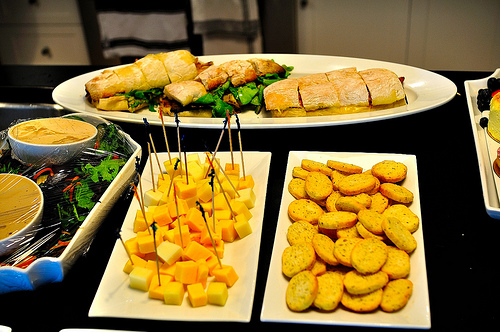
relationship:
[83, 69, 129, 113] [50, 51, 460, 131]
sandwich segment on top of plate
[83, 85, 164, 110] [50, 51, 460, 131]
sandwich segment on top of plate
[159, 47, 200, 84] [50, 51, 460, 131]
sandwich segment on top of plate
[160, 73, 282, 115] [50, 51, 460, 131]
sandwich segment on top of plate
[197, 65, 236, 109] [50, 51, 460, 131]
sandwich segment on top of plate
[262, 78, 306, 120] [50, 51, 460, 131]
sandwich segment on top of plate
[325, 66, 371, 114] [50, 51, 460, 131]
sandwich segment on top of plate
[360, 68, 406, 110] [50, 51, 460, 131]
sandwich segment on top of plate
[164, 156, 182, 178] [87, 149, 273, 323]
cheese cube on top of plate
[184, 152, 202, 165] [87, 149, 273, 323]
cheese cube on top of plate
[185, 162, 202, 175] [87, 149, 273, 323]
cheese cube on top of plate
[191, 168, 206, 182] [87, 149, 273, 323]
cheese cube on top of plate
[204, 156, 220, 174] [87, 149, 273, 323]
cheese cube on top of plate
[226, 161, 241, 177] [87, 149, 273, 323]
cheese cube on top of plate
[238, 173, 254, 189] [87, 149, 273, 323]
cheese cube on top of plate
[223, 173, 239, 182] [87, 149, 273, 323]
cheese cube on top of plate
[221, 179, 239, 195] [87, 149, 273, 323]
cheese cube on top of plate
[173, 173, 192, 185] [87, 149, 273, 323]
cheese cube on top of plate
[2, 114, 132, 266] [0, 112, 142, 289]
salad on top of plate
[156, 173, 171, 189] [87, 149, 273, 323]
cheese cube on top of plate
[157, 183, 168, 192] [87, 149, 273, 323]
cheese cube on top of plate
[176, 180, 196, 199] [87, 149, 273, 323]
cheese cube on top of plate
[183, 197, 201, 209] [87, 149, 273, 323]
cheese cube on top of plate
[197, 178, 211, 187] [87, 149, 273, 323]
cheese cube on top of plate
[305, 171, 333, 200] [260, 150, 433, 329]
bread on top of plate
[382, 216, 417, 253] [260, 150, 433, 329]
bread on top of plate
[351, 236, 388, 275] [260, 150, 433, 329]
bread on top of plate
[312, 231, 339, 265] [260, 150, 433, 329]
bread on top of plate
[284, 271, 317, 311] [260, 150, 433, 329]
bread on top of plate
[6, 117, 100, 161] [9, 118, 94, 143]
bowl contains salad dressing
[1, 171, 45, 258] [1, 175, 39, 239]
bowl contains salad dressing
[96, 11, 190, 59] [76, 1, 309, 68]
towel hanging from stove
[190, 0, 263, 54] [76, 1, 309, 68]
towel hanging from stove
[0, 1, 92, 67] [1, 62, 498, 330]
cabinet behind table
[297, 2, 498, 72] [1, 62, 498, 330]
cabinet behind table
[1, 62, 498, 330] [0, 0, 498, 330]
table located in kitchen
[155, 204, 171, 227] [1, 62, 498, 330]
cheese cube on top of table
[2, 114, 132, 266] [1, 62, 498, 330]
salad on top of table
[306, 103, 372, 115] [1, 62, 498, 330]
sandwich segment on top of table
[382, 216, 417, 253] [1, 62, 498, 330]
bread on top of table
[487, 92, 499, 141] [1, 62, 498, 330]
cake on top of table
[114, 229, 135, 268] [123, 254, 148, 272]
tootpick inside cheese cube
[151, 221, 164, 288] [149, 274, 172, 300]
tootpick inside cheese cube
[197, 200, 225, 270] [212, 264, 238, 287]
toothpick inside cheese cube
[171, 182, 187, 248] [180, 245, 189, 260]
toothpick inside cheese cube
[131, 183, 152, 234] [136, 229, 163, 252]
toothpick inside cheese cube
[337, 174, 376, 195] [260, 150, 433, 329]
bread on top of plate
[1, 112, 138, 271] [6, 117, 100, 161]
plastic covering bowl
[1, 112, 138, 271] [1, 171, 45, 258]
plastic covering bowl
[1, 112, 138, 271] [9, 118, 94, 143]
plastic covering salad dressing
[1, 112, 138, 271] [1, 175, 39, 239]
plastic covering salad dressing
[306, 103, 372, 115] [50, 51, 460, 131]
sandwich segment on top of plate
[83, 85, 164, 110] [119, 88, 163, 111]
sandwich segment has leaves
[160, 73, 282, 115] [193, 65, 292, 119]
sandwich segment has leaves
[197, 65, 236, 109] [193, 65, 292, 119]
sandwich segment has leaves